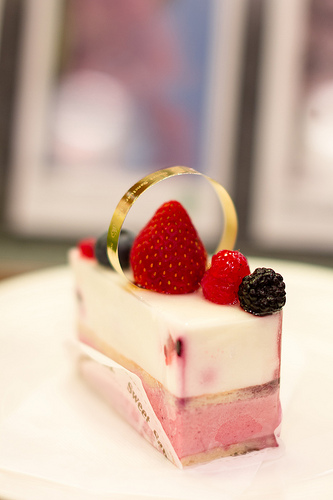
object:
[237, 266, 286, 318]
blackberry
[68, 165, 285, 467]
cake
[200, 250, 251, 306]
rasbperry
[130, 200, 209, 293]
stawberry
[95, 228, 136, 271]
blueberry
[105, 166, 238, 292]
gold ring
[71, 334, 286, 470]
paper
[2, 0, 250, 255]
picture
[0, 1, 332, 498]
background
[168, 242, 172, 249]
seeds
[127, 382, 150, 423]
sweet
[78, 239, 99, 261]
cherry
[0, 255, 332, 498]
plate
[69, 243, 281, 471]
edges